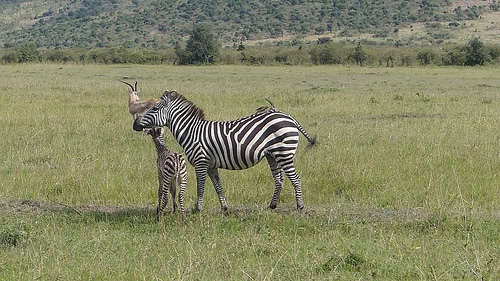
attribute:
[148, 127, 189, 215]
zebra — baby